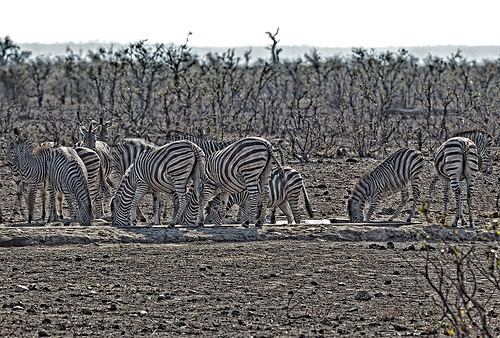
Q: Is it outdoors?
A: Yes, it is outdoors.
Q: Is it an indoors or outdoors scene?
A: It is outdoors.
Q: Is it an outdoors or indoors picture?
A: It is outdoors.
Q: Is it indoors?
A: No, it is outdoors.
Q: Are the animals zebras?
A: Yes, all the animals are zebras.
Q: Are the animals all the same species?
A: Yes, all the animals are zebras.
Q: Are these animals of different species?
A: No, all the animals are zebras.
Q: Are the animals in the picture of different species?
A: No, all the animals are zebras.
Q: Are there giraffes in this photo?
A: No, there are no giraffes.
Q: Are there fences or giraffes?
A: No, there are no giraffes or fences.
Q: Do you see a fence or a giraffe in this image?
A: No, there are no giraffes or fences.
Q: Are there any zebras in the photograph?
A: Yes, there is a zebra.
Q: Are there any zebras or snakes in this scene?
A: Yes, there is a zebra.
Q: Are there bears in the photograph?
A: No, there are no bears.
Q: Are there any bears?
A: No, there are no bears.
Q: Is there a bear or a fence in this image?
A: No, there are no bears or fences.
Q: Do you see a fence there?
A: No, there are no fences.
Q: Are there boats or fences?
A: No, there are no fences or boats.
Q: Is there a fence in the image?
A: No, there are no fences.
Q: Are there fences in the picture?
A: No, there are no fences.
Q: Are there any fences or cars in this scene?
A: No, there are no fences or cars.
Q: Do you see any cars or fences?
A: No, there are no fences or cars.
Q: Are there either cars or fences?
A: No, there are no fences or cars.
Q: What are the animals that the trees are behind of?
A: The animals are zebras.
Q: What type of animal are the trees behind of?
A: The trees are behind the zebras.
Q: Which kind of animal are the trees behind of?
A: The trees are behind the zebras.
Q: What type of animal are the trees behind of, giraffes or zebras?
A: The trees are behind zebras.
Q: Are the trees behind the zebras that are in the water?
A: Yes, the trees are behind the zebras.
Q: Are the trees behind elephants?
A: No, the trees are behind the zebras.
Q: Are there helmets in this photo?
A: No, there are no helmets.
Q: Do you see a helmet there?
A: No, there are no helmets.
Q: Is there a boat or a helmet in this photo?
A: No, there are no helmets or boats.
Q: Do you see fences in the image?
A: No, there are no fences.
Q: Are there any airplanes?
A: No, there are no airplanes.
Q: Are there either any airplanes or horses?
A: No, there are no airplanes or horses.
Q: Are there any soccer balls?
A: No, there are no soccer balls.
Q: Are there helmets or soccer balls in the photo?
A: No, there are no soccer balls or helmets.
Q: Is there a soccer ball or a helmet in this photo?
A: No, there are no soccer balls or helmets.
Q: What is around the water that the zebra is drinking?
A: The rocks are around the water.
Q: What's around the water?
A: The rocks are around the water.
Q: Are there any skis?
A: No, there are no skis.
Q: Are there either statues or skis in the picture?
A: No, there are no skis or statues.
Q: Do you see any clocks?
A: No, there are no clocks.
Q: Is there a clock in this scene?
A: No, there are no clocks.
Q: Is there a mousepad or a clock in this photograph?
A: No, there are no clocks or mouse pads.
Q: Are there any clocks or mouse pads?
A: No, there are no clocks or mouse pads.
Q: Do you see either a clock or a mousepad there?
A: No, there are no clocks or mouse pads.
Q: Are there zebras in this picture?
A: Yes, there is a zebra.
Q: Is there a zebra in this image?
A: Yes, there is a zebra.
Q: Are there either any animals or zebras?
A: Yes, there is a zebra.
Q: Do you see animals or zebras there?
A: Yes, there is a zebra.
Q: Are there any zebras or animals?
A: Yes, there is a zebra.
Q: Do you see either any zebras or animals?
A: Yes, there is a zebra.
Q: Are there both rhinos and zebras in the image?
A: No, there is a zebra but no rhinos.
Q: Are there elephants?
A: No, there are no elephants.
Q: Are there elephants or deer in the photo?
A: No, there are no elephants or deer.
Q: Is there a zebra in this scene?
A: Yes, there are zebras.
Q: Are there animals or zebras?
A: Yes, there are zebras.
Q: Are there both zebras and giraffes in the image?
A: No, there are zebras but no giraffes.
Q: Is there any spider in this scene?
A: No, there are no spiders.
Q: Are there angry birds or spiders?
A: No, there are no spiders or angry birds.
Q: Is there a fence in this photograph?
A: No, there are no fences.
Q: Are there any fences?
A: No, there are no fences.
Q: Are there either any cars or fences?
A: No, there are no fences or cars.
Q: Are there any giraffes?
A: No, there are no giraffes.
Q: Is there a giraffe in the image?
A: No, there are no giraffes.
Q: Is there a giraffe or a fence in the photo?
A: No, there are no giraffes or fences.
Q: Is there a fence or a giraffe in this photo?
A: No, there are no giraffes or fences.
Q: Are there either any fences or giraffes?
A: No, there are no giraffes or fences.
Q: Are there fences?
A: No, there are no fences.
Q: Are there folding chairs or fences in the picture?
A: No, there are no fences or folding chairs.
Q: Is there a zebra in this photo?
A: Yes, there is a zebra.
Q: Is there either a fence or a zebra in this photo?
A: Yes, there is a zebra.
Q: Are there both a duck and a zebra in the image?
A: No, there is a zebra but no ducks.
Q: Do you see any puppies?
A: No, there are no puppies.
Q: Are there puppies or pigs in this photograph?
A: No, there are no puppies or pigs.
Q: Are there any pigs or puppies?
A: No, there are no puppies or pigs.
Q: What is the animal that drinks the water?
A: The animal is a zebra.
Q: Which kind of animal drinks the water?
A: The animal is a zebra.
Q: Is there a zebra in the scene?
A: Yes, there are zebras.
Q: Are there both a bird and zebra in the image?
A: No, there are zebras but no birds.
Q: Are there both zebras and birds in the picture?
A: No, there are zebras but no birds.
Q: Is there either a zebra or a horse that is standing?
A: Yes, the zebras are standing.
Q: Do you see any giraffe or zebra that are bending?
A: Yes, the zebras are bending.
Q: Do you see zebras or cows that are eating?
A: Yes, the zebras are eating.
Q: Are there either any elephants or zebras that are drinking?
A: Yes, the zebras are drinking.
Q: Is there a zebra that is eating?
A: Yes, there are zebras that are eating.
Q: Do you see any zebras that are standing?
A: Yes, there are zebras that are standing.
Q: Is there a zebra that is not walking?
A: Yes, there are zebras that are standing.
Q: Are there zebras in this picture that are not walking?
A: Yes, there are zebras that are standing.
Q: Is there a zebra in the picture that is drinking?
A: Yes, there are zebras that are drinking.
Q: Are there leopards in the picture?
A: No, there are no leopards.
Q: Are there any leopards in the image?
A: No, there are no leopards.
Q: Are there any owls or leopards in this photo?
A: No, there are no leopards or owls.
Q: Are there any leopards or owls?
A: No, there are no leopards or owls.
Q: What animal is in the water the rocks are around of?
A: The zebras are in the water.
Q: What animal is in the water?
A: The zebras are in the water.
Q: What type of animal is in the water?
A: The animals are zebras.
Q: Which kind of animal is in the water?
A: The animals are zebras.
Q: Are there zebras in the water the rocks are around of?
A: Yes, there are zebras in the water.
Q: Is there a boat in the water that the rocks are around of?
A: No, there are zebras in the water.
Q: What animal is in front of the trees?
A: The zebras are in front of the trees.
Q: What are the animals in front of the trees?
A: The animals are zebras.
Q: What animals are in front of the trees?
A: The animals are zebras.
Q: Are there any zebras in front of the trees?
A: Yes, there are zebras in front of the trees.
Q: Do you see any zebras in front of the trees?
A: Yes, there are zebras in front of the trees.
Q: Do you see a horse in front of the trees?
A: No, there are zebras in front of the trees.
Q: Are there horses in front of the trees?
A: No, there are zebras in front of the trees.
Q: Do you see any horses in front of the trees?
A: No, there are zebras in front of the trees.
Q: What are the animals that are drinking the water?
A: The animals are zebras.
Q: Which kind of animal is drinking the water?
A: The animals are zebras.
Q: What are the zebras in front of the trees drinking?
A: The zebras are drinking water.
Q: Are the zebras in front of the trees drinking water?
A: Yes, the zebras are drinking water.